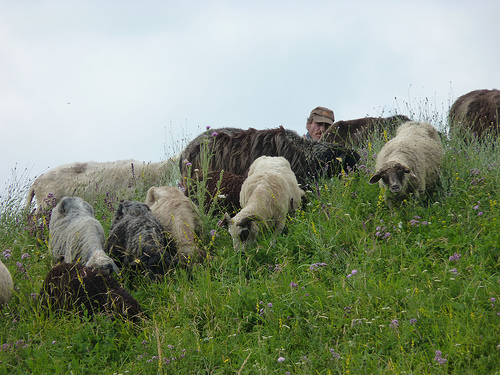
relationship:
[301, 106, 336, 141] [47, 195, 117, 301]
man behind goat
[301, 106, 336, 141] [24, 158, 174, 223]
man behind animal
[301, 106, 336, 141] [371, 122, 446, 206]
man behind goat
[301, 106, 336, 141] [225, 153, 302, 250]
man behind goat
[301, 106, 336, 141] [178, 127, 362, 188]
man behind animal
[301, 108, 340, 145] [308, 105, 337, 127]
man wears cap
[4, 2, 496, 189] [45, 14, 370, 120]
sky has clouds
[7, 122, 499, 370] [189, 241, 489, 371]
pasture has grass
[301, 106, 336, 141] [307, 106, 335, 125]
man has cap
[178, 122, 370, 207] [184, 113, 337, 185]
animal has hair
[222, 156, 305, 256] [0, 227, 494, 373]
animals grazing in grass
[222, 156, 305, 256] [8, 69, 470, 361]
animals grazing in field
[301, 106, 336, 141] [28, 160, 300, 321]
man with animals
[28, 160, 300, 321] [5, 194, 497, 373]
animals in pasture